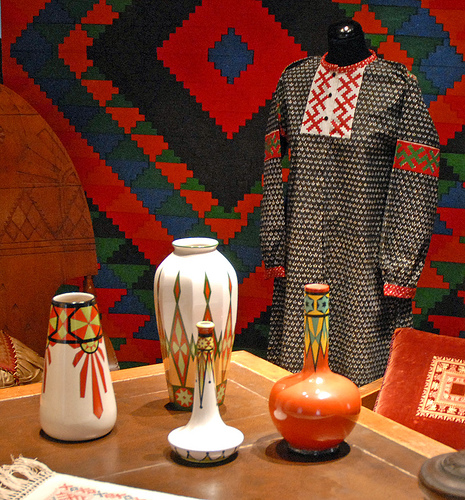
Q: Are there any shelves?
A: No, there are no shelves.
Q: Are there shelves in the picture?
A: No, there are no shelves.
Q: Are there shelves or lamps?
A: No, there are no shelves or lamps.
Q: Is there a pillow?
A: Yes, there is a pillow.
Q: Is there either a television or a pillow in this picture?
A: Yes, there is a pillow.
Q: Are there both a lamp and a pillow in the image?
A: No, there is a pillow but no lamps.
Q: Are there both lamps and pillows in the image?
A: No, there is a pillow but no lamps.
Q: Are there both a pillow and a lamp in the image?
A: No, there is a pillow but no lamps.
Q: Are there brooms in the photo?
A: No, there are no brooms.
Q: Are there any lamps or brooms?
A: No, there are no brooms or lamps.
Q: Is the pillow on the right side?
A: Yes, the pillow is on the right of the image.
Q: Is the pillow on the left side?
A: No, the pillow is on the right of the image.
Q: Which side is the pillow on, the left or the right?
A: The pillow is on the right of the image.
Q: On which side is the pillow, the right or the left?
A: The pillow is on the right of the image.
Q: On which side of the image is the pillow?
A: The pillow is on the right of the image.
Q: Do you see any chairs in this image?
A: Yes, there is a chair.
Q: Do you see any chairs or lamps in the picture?
A: Yes, there is a chair.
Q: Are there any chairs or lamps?
A: Yes, there is a chair.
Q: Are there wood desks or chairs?
A: Yes, there is a wood chair.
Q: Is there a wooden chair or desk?
A: Yes, there is a wood chair.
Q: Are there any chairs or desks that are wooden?
A: Yes, the chair is wooden.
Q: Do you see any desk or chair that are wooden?
A: Yes, the chair is wooden.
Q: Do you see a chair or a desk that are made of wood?
A: Yes, the chair is made of wood.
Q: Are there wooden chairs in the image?
A: Yes, there is a wood chair.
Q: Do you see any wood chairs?
A: Yes, there is a wood chair.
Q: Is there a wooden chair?
A: Yes, there is a wood chair.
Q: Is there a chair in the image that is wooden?
A: Yes, there is a chair that is wooden.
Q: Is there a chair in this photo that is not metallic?
A: Yes, there is a wooden chair.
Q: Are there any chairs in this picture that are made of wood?
A: Yes, there is a chair that is made of wood.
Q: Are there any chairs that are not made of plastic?
A: Yes, there is a chair that is made of wood.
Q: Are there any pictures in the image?
A: No, there are no pictures.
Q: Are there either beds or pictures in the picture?
A: No, there are no pictures or beds.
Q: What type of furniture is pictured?
A: The furniture is a chair.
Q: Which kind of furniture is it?
A: The piece of furniture is a chair.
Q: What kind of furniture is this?
A: That is a chair.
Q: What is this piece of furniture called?
A: That is a chair.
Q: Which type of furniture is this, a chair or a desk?
A: That is a chair.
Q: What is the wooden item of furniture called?
A: The piece of furniture is a chair.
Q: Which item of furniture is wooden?
A: The piece of furniture is a chair.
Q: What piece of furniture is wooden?
A: The piece of furniture is a chair.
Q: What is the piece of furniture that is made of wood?
A: The piece of furniture is a chair.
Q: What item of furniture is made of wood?
A: The piece of furniture is a chair.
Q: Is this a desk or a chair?
A: This is a chair.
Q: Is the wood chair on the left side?
A: Yes, the chair is on the left of the image.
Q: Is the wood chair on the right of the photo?
A: No, the chair is on the left of the image.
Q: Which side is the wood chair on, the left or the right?
A: The chair is on the left of the image.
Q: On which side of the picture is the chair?
A: The chair is on the left of the image.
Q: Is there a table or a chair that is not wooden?
A: No, there is a chair but it is wooden.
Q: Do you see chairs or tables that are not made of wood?
A: No, there is a chair but it is made of wood.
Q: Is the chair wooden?
A: Yes, the chair is wooden.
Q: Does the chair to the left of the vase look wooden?
A: Yes, the chair is wooden.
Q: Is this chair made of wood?
A: Yes, the chair is made of wood.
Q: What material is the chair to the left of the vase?
A: The chair is made of wood.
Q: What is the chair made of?
A: The chair is made of wood.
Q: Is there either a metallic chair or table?
A: No, there is a chair but it is wooden.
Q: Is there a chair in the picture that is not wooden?
A: No, there is a chair but it is wooden.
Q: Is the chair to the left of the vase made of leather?
A: No, the chair is made of wood.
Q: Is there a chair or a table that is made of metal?
A: No, there is a chair but it is made of wood.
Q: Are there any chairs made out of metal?
A: No, there is a chair but it is made of wood.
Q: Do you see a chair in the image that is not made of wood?
A: No, there is a chair but it is made of wood.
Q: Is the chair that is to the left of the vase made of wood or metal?
A: The chair is made of wood.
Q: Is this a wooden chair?
A: Yes, this is a wooden chair.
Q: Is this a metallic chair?
A: No, this is a wooden chair.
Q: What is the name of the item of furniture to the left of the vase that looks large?
A: The piece of furniture is a chair.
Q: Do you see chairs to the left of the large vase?
A: Yes, there is a chair to the left of the vase.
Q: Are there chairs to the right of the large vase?
A: No, the chair is to the left of the vase.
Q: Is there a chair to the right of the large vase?
A: No, the chair is to the left of the vase.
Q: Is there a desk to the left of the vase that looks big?
A: No, there is a chair to the left of the vase.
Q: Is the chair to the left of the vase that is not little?
A: Yes, the chair is to the left of the vase.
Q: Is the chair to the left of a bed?
A: No, the chair is to the left of the vase.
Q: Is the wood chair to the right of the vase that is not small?
A: No, the chair is to the left of the vase.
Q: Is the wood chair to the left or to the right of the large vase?
A: The chair is to the left of the vase.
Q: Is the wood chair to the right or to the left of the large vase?
A: The chair is to the left of the vase.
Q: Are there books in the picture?
A: No, there are no books.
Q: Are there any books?
A: No, there are no books.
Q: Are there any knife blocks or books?
A: No, there are no books or knife blocks.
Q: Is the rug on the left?
A: Yes, the rug is on the left of the image.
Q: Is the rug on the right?
A: No, the rug is on the left of the image.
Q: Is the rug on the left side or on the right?
A: The rug is on the left of the image.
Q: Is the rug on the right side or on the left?
A: The rug is on the left of the image.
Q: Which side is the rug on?
A: The rug is on the left of the image.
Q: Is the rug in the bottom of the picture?
A: Yes, the rug is in the bottom of the image.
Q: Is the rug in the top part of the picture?
A: No, the rug is in the bottom of the image.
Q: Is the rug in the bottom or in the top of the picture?
A: The rug is in the bottom of the image.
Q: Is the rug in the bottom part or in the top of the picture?
A: The rug is in the bottom of the image.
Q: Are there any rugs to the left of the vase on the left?
A: Yes, there is a rug to the left of the vase.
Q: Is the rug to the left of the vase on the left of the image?
A: Yes, the rug is to the left of the vase.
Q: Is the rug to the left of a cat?
A: No, the rug is to the left of the vase.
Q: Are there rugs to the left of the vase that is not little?
A: Yes, there is a rug to the left of the vase.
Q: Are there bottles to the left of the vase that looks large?
A: No, there is a rug to the left of the vase.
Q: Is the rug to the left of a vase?
A: Yes, the rug is to the left of a vase.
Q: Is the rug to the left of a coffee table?
A: No, the rug is to the left of a vase.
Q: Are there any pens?
A: No, there are no pens.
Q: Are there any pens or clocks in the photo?
A: No, there are no pens or clocks.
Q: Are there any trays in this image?
A: No, there are no trays.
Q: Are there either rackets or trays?
A: No, there are no trays or rackets.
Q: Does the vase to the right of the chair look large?
A: Yes, the vase is large.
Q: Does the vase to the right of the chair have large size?
A: Yes, the vase is large.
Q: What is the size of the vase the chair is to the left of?
A: The vase is large.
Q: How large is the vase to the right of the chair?
A: The vase is large.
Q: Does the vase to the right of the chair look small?
A: No, the vase is large.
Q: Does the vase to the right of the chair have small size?
A: No, the vase is large.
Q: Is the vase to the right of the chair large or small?
A: The vase is large.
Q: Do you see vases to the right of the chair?
A: Yes, there is a vase to the right of the chair.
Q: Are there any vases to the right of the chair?
A: Yes, there is a vase to the right of the chair.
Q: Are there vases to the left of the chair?
A: No, the vase is to the right of the chair.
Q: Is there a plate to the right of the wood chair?
A: No, there is a vase to the right of the chair.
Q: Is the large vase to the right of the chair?
A: Yes, the vase is to the right of the chair.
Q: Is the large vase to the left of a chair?
A: No, the vase is to the right of a chair.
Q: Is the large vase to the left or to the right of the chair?
A: The vase is to the right of the chair.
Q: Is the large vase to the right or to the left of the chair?
A: The vase is to the right of the chair.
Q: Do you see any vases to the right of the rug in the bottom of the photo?
A: Yes, there is a vase to the right of the rug.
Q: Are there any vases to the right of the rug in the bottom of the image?
A: Yes, there is a vase to the right of the rug.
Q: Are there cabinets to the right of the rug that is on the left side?
A: No, there is a vase to the right of the rug.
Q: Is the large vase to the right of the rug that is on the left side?
A: Yes, the vase is to the right of the rug.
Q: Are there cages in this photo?
A: No, there are no cages.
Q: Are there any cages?
A: No, there are no cages.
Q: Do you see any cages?
A: No, there are no cages.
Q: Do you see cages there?
A: No, there are no cages.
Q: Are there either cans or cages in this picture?
A: No, there are no cages or cans.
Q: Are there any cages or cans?
A: No, there are no cages or cans.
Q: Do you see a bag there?
A: No, there are no bags.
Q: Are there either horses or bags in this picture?
A: No, there are no bags or horses.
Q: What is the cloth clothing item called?
A: The clothing item is a costume.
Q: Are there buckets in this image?
A: No, there are no buckets.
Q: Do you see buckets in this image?
A: No, there are no buckets.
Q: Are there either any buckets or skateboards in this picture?
A: No, there are no buckets or skateboards.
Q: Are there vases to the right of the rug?
A: Yes, there is a vase to the right of the rug.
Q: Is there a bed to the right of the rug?
A: No, there is a vase to the right of the rug.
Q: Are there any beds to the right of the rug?
A: No, there is a vase to the right of the rug.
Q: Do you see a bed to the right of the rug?
A: No, there is a vase to the right of the rug.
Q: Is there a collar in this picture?
A: Yes, there is a collar.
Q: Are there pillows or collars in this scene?
A: Yes, there is a collar.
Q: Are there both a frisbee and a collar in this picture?
A: No, there is a collar but no frisbees.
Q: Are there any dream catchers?
A: No, there are no dream catchers.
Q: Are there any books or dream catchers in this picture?
A: No, there are no dream catchers or books.